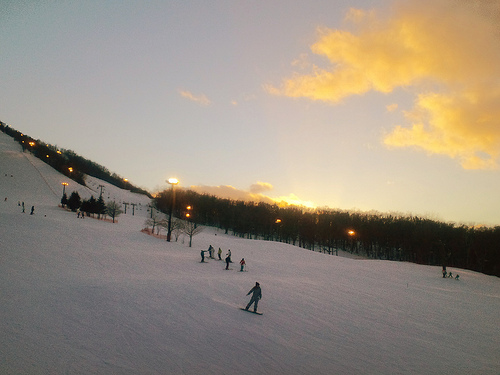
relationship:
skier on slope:
[239, 257, 246, 272] [1, 132, 499, 374]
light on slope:
[166, 175, 181, 187] [1, 132, 499, 374]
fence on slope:
[138, 227, 174, 241] [1, 132, 499, 374]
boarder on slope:
[241, 280, 263, 318] [1, 132, 499, 374]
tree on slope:
[95, 192, 107, 219] [1, 132, 499, 374]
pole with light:
[164, 184, 175, 245] [166, 175, 181, 187]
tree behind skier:
[95, 192, 107, 219] [239, 257, 246, 272]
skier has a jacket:
[239, 257, 246, 272] [240, 258, 247, 265]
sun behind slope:
[269, 194, 304, 209] [1, 132, 499, 374]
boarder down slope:
[241, 280, 263, 318] [1, 132, 499, 374]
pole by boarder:
[164, 184, 175, 245] [241, 280, 263, 318]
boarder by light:
[241, 280, 263, 318] [166, 175, 181, 187]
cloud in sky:
[271, 3, 497, 181] [2, 2, 499, 227]